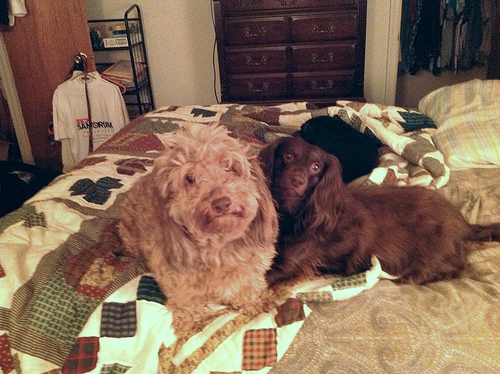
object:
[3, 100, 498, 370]
bed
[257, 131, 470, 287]
dog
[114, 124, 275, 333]
dog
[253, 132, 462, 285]
dogs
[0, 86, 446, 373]
quilt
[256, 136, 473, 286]
hair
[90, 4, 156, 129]
stand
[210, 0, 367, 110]
dresser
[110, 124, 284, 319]
fur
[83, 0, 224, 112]
wall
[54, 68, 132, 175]
shirt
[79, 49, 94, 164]
belt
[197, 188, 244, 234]
nose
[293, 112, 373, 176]
sweater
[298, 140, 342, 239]
ear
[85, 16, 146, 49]
cupboards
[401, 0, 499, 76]
clothes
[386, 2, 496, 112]
closet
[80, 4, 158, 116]
wire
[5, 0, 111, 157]
frame